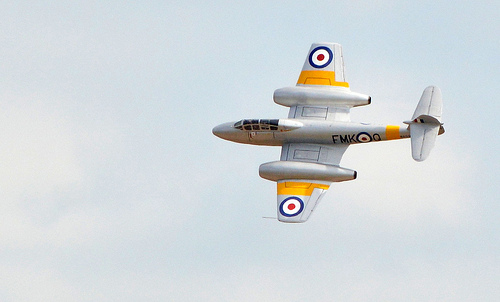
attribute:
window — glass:
[259, 116, 269, 127]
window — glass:
[270, 126, 278, 131]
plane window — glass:
[231, 112, 285, 135]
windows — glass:
[233, 116, 280, 133]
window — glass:
[235, 113, 277, 133]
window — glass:
[247, 116, 257, 126]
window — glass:
[241, 116, 279, 134]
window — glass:
[230, 111, 284, 131]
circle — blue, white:
[305, 45, 336, 70]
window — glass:
[252, 117, 279, 132]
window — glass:
[240, 124, 258, 134]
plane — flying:
[209, 35, 449, 225]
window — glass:
[267, 117, 279, 126]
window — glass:
[239, 125, 259, 143]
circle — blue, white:
[278, 193, 305, 218]